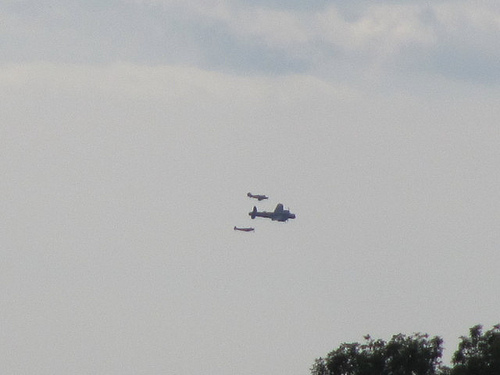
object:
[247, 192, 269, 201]
plane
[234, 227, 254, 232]
plane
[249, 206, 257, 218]
tail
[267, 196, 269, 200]
propellers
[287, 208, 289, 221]
propellers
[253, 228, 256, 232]
propellers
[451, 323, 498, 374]
trees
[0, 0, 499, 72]
clouds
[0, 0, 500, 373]
sky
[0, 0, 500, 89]
patches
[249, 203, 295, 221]
airplanes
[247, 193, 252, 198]
tail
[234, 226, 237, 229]
tail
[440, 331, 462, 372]
gap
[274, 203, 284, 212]
wing